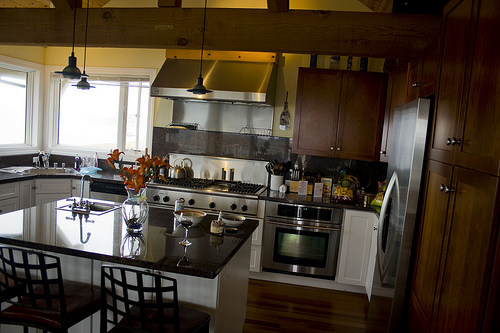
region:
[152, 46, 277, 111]
a large silver vent hood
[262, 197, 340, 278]
a modern stainless steel oven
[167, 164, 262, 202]
a six burner gas stove top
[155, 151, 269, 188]
a stainless steel backsplash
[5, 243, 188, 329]
the backs of two bar chairs at an island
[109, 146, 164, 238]
a clear vase filled with orange lilies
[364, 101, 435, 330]
the side of a stainless steel refrigerator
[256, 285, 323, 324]
a shiny brown hardwood floor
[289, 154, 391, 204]
multiple food items on the counter top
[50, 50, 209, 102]
lights hanging down from the ceiling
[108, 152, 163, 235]
A vase of orange flowers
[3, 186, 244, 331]
A kitchen island with a sink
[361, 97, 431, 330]
A stainless steel refrigerator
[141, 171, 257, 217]
A gas stove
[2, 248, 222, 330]
Two bar stools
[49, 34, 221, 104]
Three light fixtures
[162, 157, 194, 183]
A stainless steel teapot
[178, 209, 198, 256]
A wine glass sitting on the island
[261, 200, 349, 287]
A stainless steel oven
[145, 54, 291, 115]
A stainless steel range hood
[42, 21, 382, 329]
large kitchen in home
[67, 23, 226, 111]
lights hanging down from ceiling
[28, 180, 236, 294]
island in middle of kitchen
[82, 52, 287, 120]
vent and light above strove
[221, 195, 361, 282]
oven in kitchen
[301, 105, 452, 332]
built into wall fridge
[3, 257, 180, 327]
kitchen chairs by island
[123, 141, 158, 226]
flowers in middle of kitchen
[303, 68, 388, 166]
cupboards in kitchen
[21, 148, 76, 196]
metal sink in corner of the kitchen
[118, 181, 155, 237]
clear vase on the island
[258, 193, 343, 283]
stainless steel oven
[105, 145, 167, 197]
orange flowers in the vase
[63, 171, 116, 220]
sink inset into the island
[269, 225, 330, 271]
windowed door of the oven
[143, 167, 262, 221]
stainless steel cooking range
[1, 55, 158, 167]
windows covering the corner of the room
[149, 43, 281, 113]
stainless steel stove hood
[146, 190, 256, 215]
six black knobs on the stove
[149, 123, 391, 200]
black backsplash in the kitchen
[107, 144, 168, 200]
The orange flowers in the vase.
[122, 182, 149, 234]
The glass vase holding the orange flowers.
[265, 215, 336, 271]
The door of the oven.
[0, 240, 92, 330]
The chair at the kitchen island on the left.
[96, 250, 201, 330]
The chair at the kitchen island on the right.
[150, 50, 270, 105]
The roof over the range/stove.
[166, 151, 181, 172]
The tea kettle on the stove.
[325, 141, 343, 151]
The knobs on the cabinet to the right of the stove.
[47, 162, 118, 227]
The sink in the corner of the kitchen island.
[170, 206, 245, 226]
The two bowls on the kitchen island.